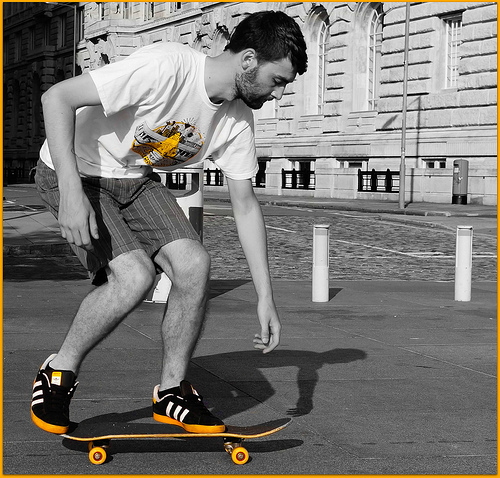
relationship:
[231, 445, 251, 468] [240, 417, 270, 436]
wheel on skateboard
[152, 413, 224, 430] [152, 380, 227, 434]
trim on shoe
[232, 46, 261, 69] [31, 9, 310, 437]
ear on guy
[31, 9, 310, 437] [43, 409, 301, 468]
guy on skateboard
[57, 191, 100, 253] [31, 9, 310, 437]
hand on guy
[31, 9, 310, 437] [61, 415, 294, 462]
guy on skateboard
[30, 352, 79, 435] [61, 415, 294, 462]
shoe on skateboard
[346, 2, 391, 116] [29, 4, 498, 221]
window on building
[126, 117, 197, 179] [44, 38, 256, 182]
logo on shirt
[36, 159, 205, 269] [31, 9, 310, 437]
shorts on guy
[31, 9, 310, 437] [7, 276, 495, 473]
guy skateboarding on sidewalk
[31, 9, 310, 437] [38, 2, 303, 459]
guy getting exercise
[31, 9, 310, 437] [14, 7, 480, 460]
guy enjoying day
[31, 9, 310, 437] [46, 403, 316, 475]
guy using skateboard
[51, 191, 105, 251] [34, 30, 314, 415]
hand belongs to man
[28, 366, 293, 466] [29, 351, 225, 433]
accent on sneakers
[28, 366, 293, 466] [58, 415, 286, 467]
accent on skateboard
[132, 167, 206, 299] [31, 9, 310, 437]
recepticle behind guy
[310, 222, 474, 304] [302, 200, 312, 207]
posts prevent traffic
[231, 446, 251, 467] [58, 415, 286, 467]
wheel belongs to skateboard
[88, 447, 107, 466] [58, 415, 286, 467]
yellow wheel belongs to skateboard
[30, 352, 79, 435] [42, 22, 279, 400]
shoe belong to guy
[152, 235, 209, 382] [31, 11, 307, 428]
leg belongs to guy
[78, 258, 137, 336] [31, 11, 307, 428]
leg belongs to guy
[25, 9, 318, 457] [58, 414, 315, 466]
guy riding on skateboard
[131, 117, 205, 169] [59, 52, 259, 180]
logo on shirt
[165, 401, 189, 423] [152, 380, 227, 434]
stripes on shoe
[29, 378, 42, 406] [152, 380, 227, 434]
stripes on shoe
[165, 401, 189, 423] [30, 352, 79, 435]
stripes on shoe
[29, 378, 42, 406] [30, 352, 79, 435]
stripes on shoe